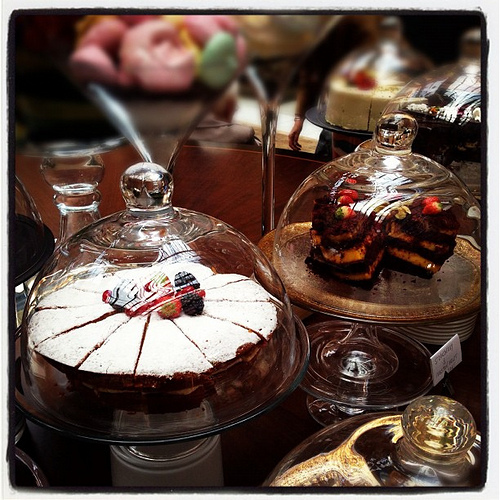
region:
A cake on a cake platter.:
[25, 237, 297, 416]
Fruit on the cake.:
[90, 259, 199, 323]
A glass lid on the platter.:
[32, 157, 304, 429]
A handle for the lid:
[400, 396, 482, 457]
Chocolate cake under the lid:
[305, 169, 467, 291]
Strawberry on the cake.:
[330, 201, 367, 221]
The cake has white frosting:
[47, 317, 201, 384]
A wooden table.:
[219, 159, 250, 204]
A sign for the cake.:
[422, 330, 475, 390]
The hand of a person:
[287, 106, 309, 153]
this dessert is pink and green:
[69, 24, 252, 95]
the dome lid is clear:
[38, 159, 313, 409]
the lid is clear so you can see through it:
[303, 106, 485, 316]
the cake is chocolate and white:
[135, 305, 216, 420]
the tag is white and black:
[408, 328, 477, 391]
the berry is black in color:
[181, 284, 213, 319]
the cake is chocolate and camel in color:
[331, 226, 388, 291]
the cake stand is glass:
[296, 322, 453, 434]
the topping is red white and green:
[417, 196, 452, 216]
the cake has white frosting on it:
[318, 84, 386, 132]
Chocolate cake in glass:
[322, 186, 454, 283]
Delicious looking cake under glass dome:
[39, 261, 282, 406]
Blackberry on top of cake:
[182, 297, 205, 311]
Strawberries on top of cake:
[337, 184, 354, 221]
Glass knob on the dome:
[374, 104, 419, 155]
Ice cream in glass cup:
[77, 17, 236, 90]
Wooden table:
[194, 143, 263, 231]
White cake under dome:
[322, 87, 377, 128]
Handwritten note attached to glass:
[431, 337, 468, 378]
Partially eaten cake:
[364, 213, 432, 284]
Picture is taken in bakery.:
[43, 36, 445, 476]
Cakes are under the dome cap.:
[35, 188, 460, 379]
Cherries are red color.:
[333, 178, 443, 217]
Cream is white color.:
[62, 309, 139, 354]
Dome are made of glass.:
[58, 210, 296, 400]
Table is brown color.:
[191, 147, 259, 208]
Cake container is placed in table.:
[288, 275, 452, 437]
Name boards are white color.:
[426, 331, 464, 378]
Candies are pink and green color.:
[68, 29, 224, 89]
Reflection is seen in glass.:
[54, 221, 251, 343]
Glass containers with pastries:
[44, 111, 464, 469]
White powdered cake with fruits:
[36, 258, 281, 401]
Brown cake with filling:
[297, 135, 460, 289]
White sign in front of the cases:
[414, 328, 476, 405]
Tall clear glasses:
[93, 18, 312, 230]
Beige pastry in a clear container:
[316, 34, 437, 134]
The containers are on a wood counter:
[48, 139, 443, 449]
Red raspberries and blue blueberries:
[103, 260, 219, 317]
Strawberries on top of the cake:
[321, 157, 453, 217]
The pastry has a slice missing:
[296, 153, 471, 297]